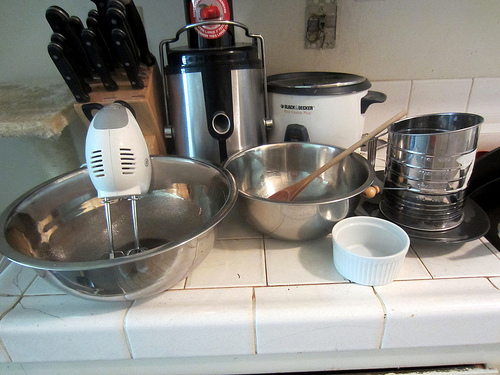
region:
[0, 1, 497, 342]
A bunch of kitchen supplies on a counter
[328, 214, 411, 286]
White porcelain souffle bowl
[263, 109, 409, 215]
Long wooden mixing spoon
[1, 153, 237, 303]
Dirty stainless steel mixing bowl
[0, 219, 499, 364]
Dirty grout between the tiles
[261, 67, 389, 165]
Small crock pot against the wall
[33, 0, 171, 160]
Wood brick with a bunch of knives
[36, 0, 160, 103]
Knives with black handles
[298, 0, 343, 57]
Broken outlet on the wall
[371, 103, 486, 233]
Old fashioned flour sifter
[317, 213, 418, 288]
White bowl on the counter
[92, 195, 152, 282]
Blades on the mixer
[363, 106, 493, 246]
Sifter on the counter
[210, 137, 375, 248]
Silver bowl on the counter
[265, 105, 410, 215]
Wooden spoon in the bowl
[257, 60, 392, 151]
Crockpot on the counter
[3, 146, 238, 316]
Silver bowl on the counter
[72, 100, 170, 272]
Mixer in the bowl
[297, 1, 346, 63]
Socket on the wall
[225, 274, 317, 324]
The kitchen counter is white.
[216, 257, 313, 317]
The kitchen counter is made from tile.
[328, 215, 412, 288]
The bowl is white.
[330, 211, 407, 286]
The bowl is round.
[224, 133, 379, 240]
The bowl is silver.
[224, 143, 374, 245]
The bowl is round.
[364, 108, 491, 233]
The flour sifter is on the table.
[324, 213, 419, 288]
The bowl is on the counter.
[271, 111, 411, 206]
The wooden spoon is in the bowl.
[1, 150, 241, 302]
a silver mixing bowl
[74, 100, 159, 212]
a white and gray mixer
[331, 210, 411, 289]
a white container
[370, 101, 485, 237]
a silver measuring cup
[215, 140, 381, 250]
a silver bowl with a spoon in it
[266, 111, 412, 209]
a wooden spoon in a bowl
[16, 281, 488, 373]
a white tile countertop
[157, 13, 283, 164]
a silver and black container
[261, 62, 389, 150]
a Black & Decker crock pot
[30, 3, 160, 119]
a wooden block of knives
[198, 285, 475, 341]
The counter is the color white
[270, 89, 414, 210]
A wooden spoon in the bowl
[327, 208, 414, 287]
A white dish on the counter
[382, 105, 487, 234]
A silver sifter on the counter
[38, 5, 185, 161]
A set of knives on the counter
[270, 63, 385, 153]
A crock pot on the counter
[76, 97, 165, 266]
A mixer in the bowl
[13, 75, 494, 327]
A preparation to bake something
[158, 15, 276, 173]
A silver colored appliance on the counter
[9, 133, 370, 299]
a set of bowls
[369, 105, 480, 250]
silver sifter on the side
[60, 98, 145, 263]
a white hand mixer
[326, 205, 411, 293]
a small white ramekin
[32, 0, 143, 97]
a set of knives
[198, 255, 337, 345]
tiles on the counter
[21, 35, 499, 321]
a scene of a kitchen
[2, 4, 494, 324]
random appliances for cooking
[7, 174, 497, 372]
a white counter top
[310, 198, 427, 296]
a white bowl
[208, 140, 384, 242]
a silver bowl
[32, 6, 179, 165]
a set of knifes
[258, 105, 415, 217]
a wooden spoon